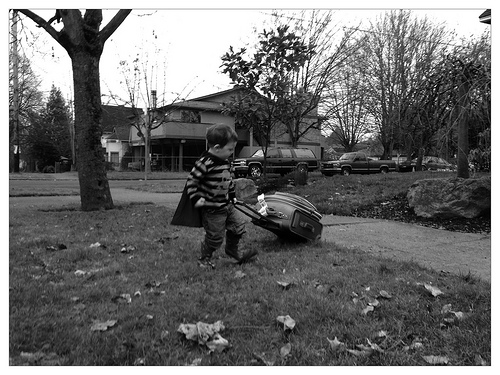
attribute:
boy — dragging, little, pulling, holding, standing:
[196, 117, 237, 255]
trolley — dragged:
[246, 172, 340, 255]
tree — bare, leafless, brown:
[57, 13, 141, 244]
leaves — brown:
[113, 285, 323, 372]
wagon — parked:
[248, 146, 336, 176]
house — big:
[176, 82, 311, 166]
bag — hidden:
[233, 171, 264, 201]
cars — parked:
[285, 143, 453, 190]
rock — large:
[408, 169, 499, 243]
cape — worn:
[145, 174, 244, 276]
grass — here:
[47, 255, 216, 370]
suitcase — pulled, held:
[264, 196, 328, 237]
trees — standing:
[320, 40, 499, 160]